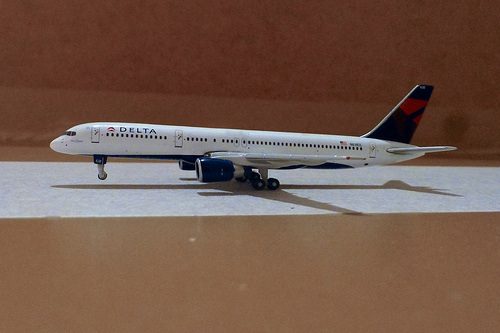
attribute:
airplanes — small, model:
[29, 90, 499, 202]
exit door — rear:
[367, 141, 376, 161]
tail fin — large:
[376, 78, 436, 150]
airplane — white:
[26, 43, 465, 222]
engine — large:
[195, 156, 235, 183]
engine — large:
[178, 159, 195, 169]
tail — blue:
[362, 82, 437, 145]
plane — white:
[44, 78, 462, 198]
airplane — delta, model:
[46, 83, 458, 193]